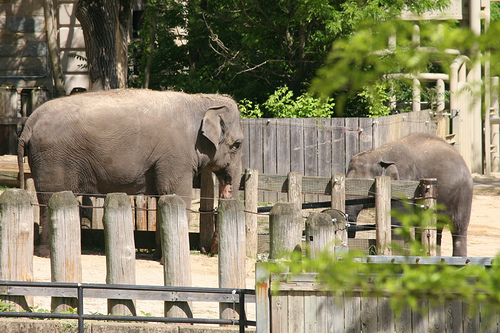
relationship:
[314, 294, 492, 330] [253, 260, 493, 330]
shadow on wall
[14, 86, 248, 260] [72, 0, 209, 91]
elephant near tree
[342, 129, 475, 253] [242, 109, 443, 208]
elephant in fence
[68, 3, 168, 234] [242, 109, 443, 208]
tree in fence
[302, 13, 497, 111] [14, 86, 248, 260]
branch near elephant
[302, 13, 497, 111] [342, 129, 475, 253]
branch near elephant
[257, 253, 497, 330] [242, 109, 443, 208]
fence around fence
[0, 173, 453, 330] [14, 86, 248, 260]
fence near elephant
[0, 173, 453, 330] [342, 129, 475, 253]
fence near elephant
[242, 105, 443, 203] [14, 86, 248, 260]
fence behind elephant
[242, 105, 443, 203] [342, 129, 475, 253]
fence behind elephant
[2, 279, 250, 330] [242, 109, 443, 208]
railing near fence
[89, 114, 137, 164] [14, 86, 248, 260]
skin on elephant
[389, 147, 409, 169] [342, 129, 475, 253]
skin on elephant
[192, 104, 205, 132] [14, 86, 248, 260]
skin on elephant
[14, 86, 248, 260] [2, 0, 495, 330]
elephant in zoo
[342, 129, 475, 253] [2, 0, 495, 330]
elephant in zoo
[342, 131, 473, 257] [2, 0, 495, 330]
elephant in zoo